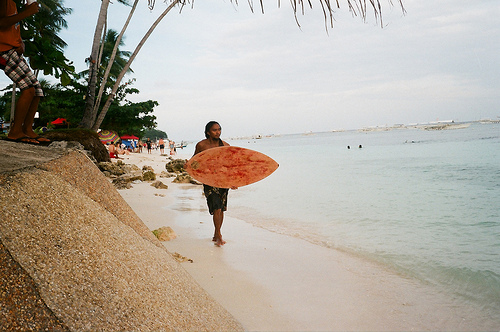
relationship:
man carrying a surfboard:
[184, 120, 279, 247] [180, 145, 283, 185]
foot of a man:
[8, 130, 40, 146] [1, 29, 53, 146]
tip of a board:
[263, 155, 280, 176] [181, 142, 281, 187]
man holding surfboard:
[189, 114, 459, 139] [176, 143, 285, 192]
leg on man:
[210, 208, 224, 247] [184, 120, 279, 247]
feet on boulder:
[1, 123, 51, 145] [18, 162, 169, 330]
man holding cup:
[1, 0, 53, 146] [23, 0, 40, 7]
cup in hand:
[23, 0, 40, 7] [21, 0, 37, 17]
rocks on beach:
[108, 199, 235, 307] [204, 124, 484, 289]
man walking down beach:
[184, 120, 279, 247] [103, 202, 478, 330]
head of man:
[345, 144, 352, 150] [344, 140, 354, 160]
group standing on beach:
[105, 137, 184, 154] [90, 129, 495, 330]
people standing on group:
[108, 133, 178, 153] [105, 137, 184, 154]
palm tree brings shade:
[31, 2, 171, 171] [27, 122, 75, 148]